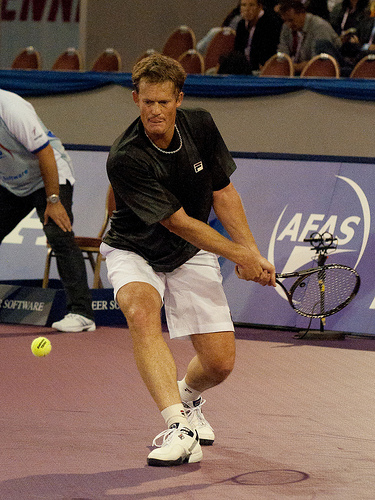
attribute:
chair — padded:
[9, 42, 47, 68]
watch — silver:
[47, 193, 59, 204]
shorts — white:
[90, 232, 281, 283]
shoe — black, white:
[147, 424, 204, 465]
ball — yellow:
[30, 335, 50, 358]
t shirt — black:
[100, 109, 236, 273]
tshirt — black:
[96, 105, 237, 275]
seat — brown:
[257, 44, 293, 82]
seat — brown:
[298, 49, 337, 81]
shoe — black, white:
[49, 312, 99, 335]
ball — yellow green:
[29, 333, 52, 358]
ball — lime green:
[27, 333, 54, 361]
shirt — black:
[101, 107, 237, 272]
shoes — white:
[143, 422, 205, 469]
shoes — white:
[166, 388, 219, 444]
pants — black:
[10, 203, 110, 323]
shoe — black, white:
[146, 411, 206, 469]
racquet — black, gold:
[270, 259, 365, 324]